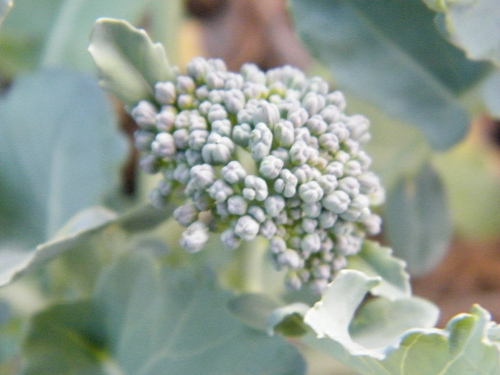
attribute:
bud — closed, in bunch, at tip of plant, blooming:
[219, 158, 248, 185]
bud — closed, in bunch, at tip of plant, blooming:
[240, 173, 271, 204]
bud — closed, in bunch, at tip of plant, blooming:
[200, 130, 238, 166]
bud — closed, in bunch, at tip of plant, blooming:
[189, 161, 216, 192]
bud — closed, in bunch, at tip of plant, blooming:
[259, 154, 287, 179]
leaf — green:
[285, 0, 499, 157]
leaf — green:
[273, 265, 499, 373]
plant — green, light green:
[83, 14, 415, 317]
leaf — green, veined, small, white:
[87, 15, 184, 119]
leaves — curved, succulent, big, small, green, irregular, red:
[86, 15, 176, 109]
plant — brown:
[185, 0, 314, 75]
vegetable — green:
[129, 53, 386, 291]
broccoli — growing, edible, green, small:
[129, 55, 384, 295]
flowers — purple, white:
[470, 108, 499, 172]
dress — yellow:
[180, 19, 205, 73]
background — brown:
[186, 2, 314, 73]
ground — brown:
[371, 224, 498, 330]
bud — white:
[186, 57, 213, 85]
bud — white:
[225, 87, 244, 113]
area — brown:
[186, 3, 310, 72]